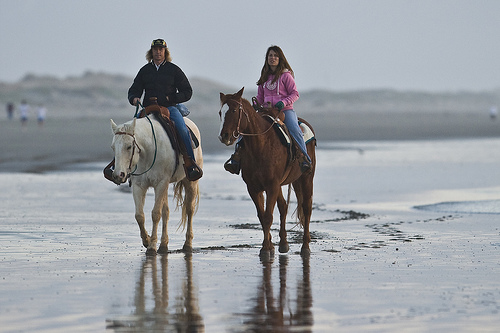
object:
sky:
[0, 0, 499, 95]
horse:
[214, 87, 324, 267]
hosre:
[215, 86, 318, 262]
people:
[36, 100, 49, 129]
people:
[17, 97, 29, 126]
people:
[4, 99, 16, 122]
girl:
[223, 46, 312, 176]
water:
[400, 187, 486, 220]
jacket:
[251, 67, 301, 115]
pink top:
[254, 68, 299, 115]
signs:
[291, 211, 460, 258]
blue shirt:
[16, 102, 32, 116]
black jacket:
[126, 59, 192, 109]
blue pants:
[227, 109, 312, 165]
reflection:
[105, 255, 206, 332]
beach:
[0, 69, 499, 332]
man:
[104, 38, 202, 184]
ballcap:
[149, 38, 167, 48]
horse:
[108, 114, 204, 255]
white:
[216, 102, 230, 136]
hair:
[254, 45, 295, 86]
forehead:
[219, 96, 233, 133]